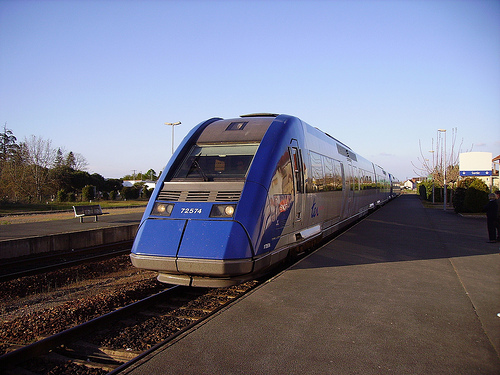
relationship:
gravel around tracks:
[3, 275, 67, 338] [2, 288, 193, 365]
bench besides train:
[68, 201, 113, 226] [125, 109, 408, 282]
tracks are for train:
[2, 288, 193, 365] [125, 109, 408, 282]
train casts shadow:
[125, 109, 408, 282] [298, 196, 492, 270]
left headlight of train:
[211, 200, 243, 219] [125, 109, 408, 282]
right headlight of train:
[145, 200, 175, 221] [125, 109, 408, 282]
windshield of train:
[178, 142, 261, 184] [125, 109, 408, 282]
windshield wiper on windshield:
[189, 156, 211, 185] [178, 142, 261, 184]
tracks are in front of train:
[2, 288, 193, 365] [125, 109, 408, 282]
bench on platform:
[68, 201, 113, 226] [1, 209, 146, 257]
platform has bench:
[1, 209, 146, 257] [68, 201, 113, 226]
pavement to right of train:
[160, 200, 492, 367] [125, 109, 408, 282]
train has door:
[125, 109, 408, 282] [287, 138, 310, 234]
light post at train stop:
[433, 121, 453, 212] [455, 138, 500, 216]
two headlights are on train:
[147, 197, 240, 226] [125, 109, 408, 282]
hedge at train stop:
[443, 173, 493, 218] [455, 138, 500, 216]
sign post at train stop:
[456, 149, 496, 180] [455, 138, 500, 216]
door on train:
[287, 138, 310, 234] [125, 109, 408, 282]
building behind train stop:
[491, 155, 499, 183] [455, 138, 500, 216]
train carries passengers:
[125, 109, 408, 282] [296, 150, 404, 197]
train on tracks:
[125, 109, 408, 282] [2, 288, 193, 365]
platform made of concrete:
[1, 209, 146, 257] [4, 229, 121, 254]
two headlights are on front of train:
[147, 197, 240, 226] [125, 109, 408, 282]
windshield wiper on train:
[189, 156, 211, 185] [125, 109, 408, 282]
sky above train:
[1, 7, 497, 121] [125, 109, 408, 282]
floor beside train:
[234, 252, 483, 361] [125, 109, 408, 282]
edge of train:
[125, 251, 243, 282] [125, 109, 408, 282]